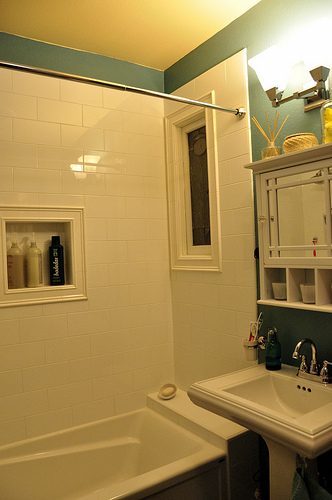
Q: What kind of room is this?
A: A bathroom.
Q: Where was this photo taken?
A: A bathroom.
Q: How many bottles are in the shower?
A: Three.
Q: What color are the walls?
A: Blue.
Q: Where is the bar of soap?
A: In the bath.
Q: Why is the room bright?
A: The lights are on.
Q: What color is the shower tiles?
A: White.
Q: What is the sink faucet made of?
A: Metal.